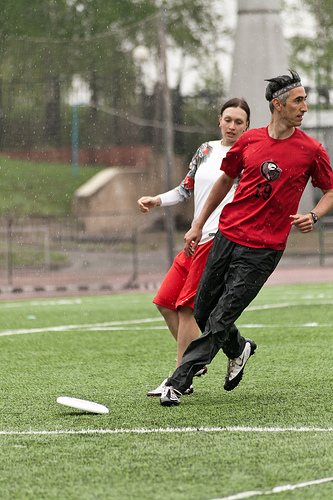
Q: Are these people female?
A: No, they are both male and female.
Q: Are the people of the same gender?
A: No, they are both male and female.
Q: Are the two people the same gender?
A: No, they are both male and female.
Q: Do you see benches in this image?
A: No, there are no benches.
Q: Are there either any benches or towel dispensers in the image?
A: No, there are no benches or towel dispensers.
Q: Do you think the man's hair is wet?
A: Yes, the hair is wet.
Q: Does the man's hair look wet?
A: Yes, the hair is wet.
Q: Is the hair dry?
A: No, the hair is wet.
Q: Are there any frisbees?
A: Yes, there is a frisbee.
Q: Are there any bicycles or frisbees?
A: Yes, there is a frisbee.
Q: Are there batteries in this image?
A: No, there are no batteries.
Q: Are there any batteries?
A: No, there are no batteries.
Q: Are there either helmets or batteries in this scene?
A: No, there are no batteries or helmets.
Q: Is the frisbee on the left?
A: Yes, the frisbee is on the left of the image.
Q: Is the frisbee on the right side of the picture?
A: No, the frisbee is on the left of the image.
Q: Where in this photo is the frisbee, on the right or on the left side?
A: The frisbee is on the left of the image.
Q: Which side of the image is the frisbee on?
A: The frisbee is on the left of the image.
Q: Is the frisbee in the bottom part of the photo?
A: Yes, the frisbee is in the bottom of the image.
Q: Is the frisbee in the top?
A: No, the frisbee is in the bottom of the image.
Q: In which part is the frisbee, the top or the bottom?
A: The frisbee is in the bottom of the image.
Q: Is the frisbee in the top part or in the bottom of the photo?
A: The frisbee is in the bottom of the image.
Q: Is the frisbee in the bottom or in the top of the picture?
A: The frisbee is in the bottom of the image.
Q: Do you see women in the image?
A: Yes, there is a woman.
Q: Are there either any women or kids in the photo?
A: Yes, there is a woman.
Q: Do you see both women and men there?
A: Yes, there are both a woman and a man.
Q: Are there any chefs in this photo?
A: No, there are no chefs.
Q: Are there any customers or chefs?
A: No, there are no chefs or customers.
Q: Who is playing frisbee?
A: The woman is playing frisbee.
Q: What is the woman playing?
A: The woman is playing frisbee.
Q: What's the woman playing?
A: The woman is playing frisbee.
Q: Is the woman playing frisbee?
A: Yes, the woman is playing frisbee.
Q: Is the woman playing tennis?
A: No, the woman is playing frisbee.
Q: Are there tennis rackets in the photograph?
A: No, there are no tennis rackets.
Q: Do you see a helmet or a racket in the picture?
A: No, there are no rackets or helmets.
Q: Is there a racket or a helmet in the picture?
A: No, there are no rackets or helmets.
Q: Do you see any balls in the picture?
A: No, there are no balls.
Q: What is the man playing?
A: The man is playing frisbee.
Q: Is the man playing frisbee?
A: Yes, the man is playing frisbee.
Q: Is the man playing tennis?
A: No, the man is playing frisbee.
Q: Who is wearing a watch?
A: The man is wearing a watch.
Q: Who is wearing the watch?
A: The man is wearing a watch.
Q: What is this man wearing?
A: The man is wearing a watch.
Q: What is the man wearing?
A: The man is wearing a watch.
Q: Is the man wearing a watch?
A: Yes, the man is wearing a watch.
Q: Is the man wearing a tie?
A: No, the man is wearing a watch.